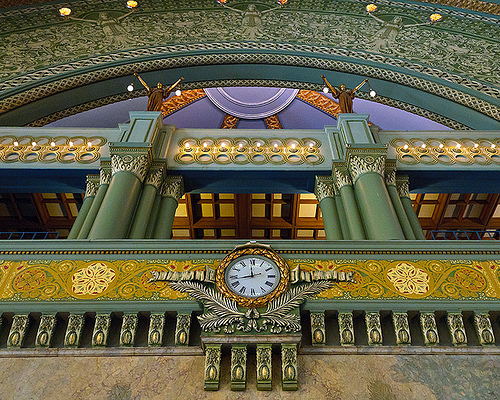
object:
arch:
[0, 0, 499, 399]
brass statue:
[131, 71, 186, 113]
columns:
[352, 169, 407, 241]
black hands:
[248, 265, 254, 278]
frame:
[222, 252, 282, 299]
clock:
[212, 238, 291, 310]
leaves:
[169, 280, 246, 321]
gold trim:
[213, 247, 291, 310]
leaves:
[258, 279, 335, 320]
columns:
[84, 169, 143, 241]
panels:
[219, 202, 237, 219]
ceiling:
[167, 193, 327, 240]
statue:
[316, 73, 370, 114]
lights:
[365, 87, 377, 100]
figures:
[383, 258, 431, 295]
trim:
[343, 143, 391, 150]